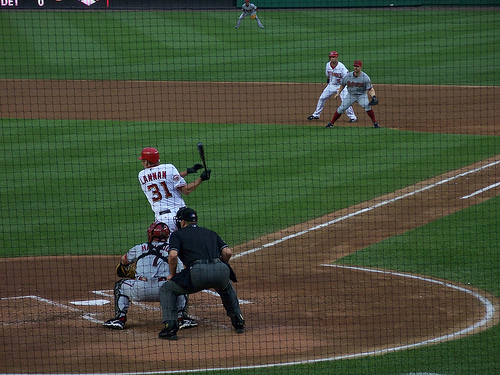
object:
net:
[0, 0, 500, 375]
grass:
[4, 6, 498, 86]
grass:
[201, 196, 498, 373]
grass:
[4, 118, 498, 256]